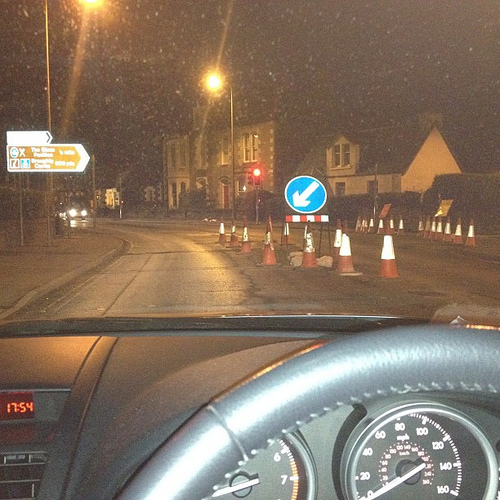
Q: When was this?
A: Nighttime.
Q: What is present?
A: Buildings.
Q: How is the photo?
A: Blurry.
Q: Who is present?
A: Nobody.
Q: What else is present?
A: A car.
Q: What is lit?
A: Lights.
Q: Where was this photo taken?
A: On a roadway.